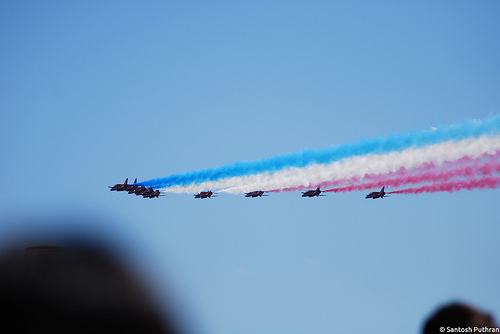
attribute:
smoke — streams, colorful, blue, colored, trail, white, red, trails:
[161, 105, 499, 199]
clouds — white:
[168, 113, 482, 213]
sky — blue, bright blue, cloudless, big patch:
[7, 7, 489, 331]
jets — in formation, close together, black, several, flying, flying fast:
[111, 172, 392, 205]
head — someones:
[13, 227, 165, 333]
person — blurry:
[5, 243, 128, 333]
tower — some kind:
[29, 240, 60, 250]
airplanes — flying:
[109, 169, 389, 207]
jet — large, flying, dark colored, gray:
[192, 186, 216, 207]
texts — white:
[434, 323, 498, 332]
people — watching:
[6, 231, 494, 334]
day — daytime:
[9, 9, 496, 321]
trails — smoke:
[168, 111, 494, 204]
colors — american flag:
[146, 120, 496, 192]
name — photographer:
[443, 325, 489, 334]